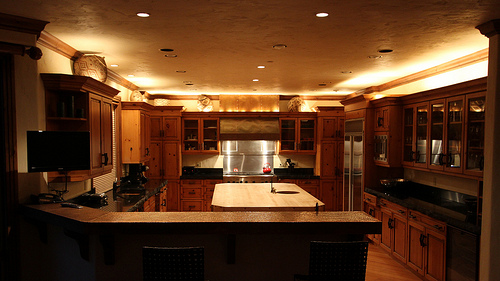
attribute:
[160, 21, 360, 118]
ceiling — large white 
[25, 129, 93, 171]
tv monitor — display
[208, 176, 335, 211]
table — brown 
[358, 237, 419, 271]
floor — display